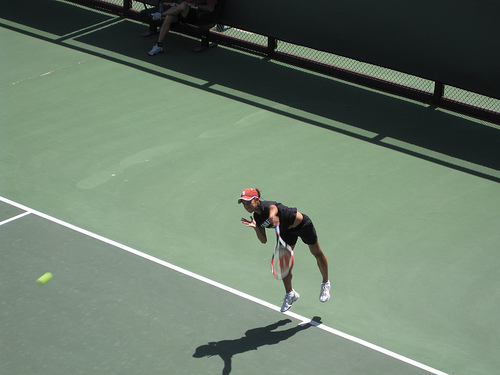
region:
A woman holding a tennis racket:
[219, 157, 326, 342]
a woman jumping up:
[216, 185, 356, 336]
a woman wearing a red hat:
[236, 182, 256, 224]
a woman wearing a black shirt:
[216, 180, 337, 258]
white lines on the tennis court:
[15, 184, 121, 265]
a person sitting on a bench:
[143, 1, 235, 61]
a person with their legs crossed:
[136, 5, 205, 65]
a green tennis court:
[75, 85, 172, 211]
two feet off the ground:
[258, 274, 343, 327]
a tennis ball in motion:
[28, 250, 62, 304]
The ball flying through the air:
[29, 262, 61, 289]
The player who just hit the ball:
[228, 185, 334, 315]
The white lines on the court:
[1, 196, 435, 373]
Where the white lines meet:
[18, 204, 45, 222]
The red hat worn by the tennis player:
[236, 180, 260, 210]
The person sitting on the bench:
[146, 0, 213, 59]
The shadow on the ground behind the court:
[3, 0, 499, 183]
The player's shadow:
[187, 312, 324, 372]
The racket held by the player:
[265, 224, 299, 281]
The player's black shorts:
[279, 217, 321, 246]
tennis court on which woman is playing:
[5, 3, 493, 373]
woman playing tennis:
[241, 183, 336, 315]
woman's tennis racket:
[266, 221, 301, 283]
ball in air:
[30, 264, 59, 285]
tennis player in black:
[233, 180, 342, 317]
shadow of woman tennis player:
[188, 314, 323, 374]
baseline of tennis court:
[2, 195, 212, 374]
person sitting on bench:
[145, 0, 213, 61]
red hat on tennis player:
[238, 185, 258, 204]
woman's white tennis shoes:
[281, 280, 336, 317]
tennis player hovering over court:
[232, 181, 337, 316]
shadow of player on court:
[190, 316, 319, 373]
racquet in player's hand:
[264, 216, 296, 290]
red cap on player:
[235, 183, 265, 206]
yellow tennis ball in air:
[26, 257, 63, 291]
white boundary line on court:
[63, 226, 141, 244]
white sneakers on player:
[273, 277, 332, 322]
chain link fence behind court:
[321, 32, 435, 73]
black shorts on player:
[273, 212, 321, 250]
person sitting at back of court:
[139, 7, 203, 59]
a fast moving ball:
[36, 267, 61, 287]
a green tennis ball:
[30, 267, 56, 286]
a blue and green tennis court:
[21, 112, 473, 352]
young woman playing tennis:
[38, 124, 477, 369]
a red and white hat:
[229, 177, 274, 214]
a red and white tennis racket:
[264, 220, 309, 290]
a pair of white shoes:
[267, 275, 349, 315]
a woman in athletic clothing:
[235, 175, 350, 320]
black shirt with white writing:
[244, 199, 304, 236]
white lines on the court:
[8, 188, 75, 240]